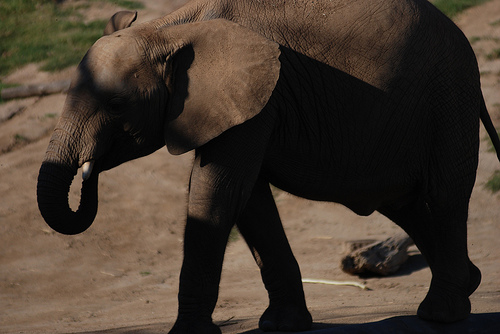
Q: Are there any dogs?
A: No, there are no dogs.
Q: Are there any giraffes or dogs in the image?
A: No, there are no dogs or giraffes.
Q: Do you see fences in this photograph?
A: No, there are no fences.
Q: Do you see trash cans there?
A: No, there are no trash cans.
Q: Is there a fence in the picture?
A: No, there are no fences.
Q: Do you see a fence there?
A: No, there are no fences.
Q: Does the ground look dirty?
A: Yes, the ground is dirty.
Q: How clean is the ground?
A: The ground is dirty.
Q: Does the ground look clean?
A: No, the ground is dirty.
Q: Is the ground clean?
A: No, the ground is dirty.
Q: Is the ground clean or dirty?
A: The ground is dirty.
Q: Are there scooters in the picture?
A: No, there are no scooters.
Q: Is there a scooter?
A: No, there are no scooters.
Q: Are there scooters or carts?
A: No, there are no scooters or carts.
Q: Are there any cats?
A: No, there are no cats.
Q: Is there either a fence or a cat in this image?
A: No, there are no fences or cats.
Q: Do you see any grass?
A: Yes, there is grass.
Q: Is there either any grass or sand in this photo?
A: Yes, there is grass.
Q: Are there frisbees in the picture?
A: No, there are no frisbees.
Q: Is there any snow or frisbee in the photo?
A: No, there are no frisbees or snow.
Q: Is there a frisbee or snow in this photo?
A: No, there are no frisbees or snow.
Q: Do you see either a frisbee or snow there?
A: No, there are no frisbees or snow.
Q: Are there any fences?
A: No, there are no fences.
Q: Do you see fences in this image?
A: No, there are no fences.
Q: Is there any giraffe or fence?
A: No, there are no fences or giraffes.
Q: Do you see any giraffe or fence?
A: No, there are no fences or giraffes.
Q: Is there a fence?
A: No, there are no fences.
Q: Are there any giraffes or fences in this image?
A: No, there are no fences or giraffes.